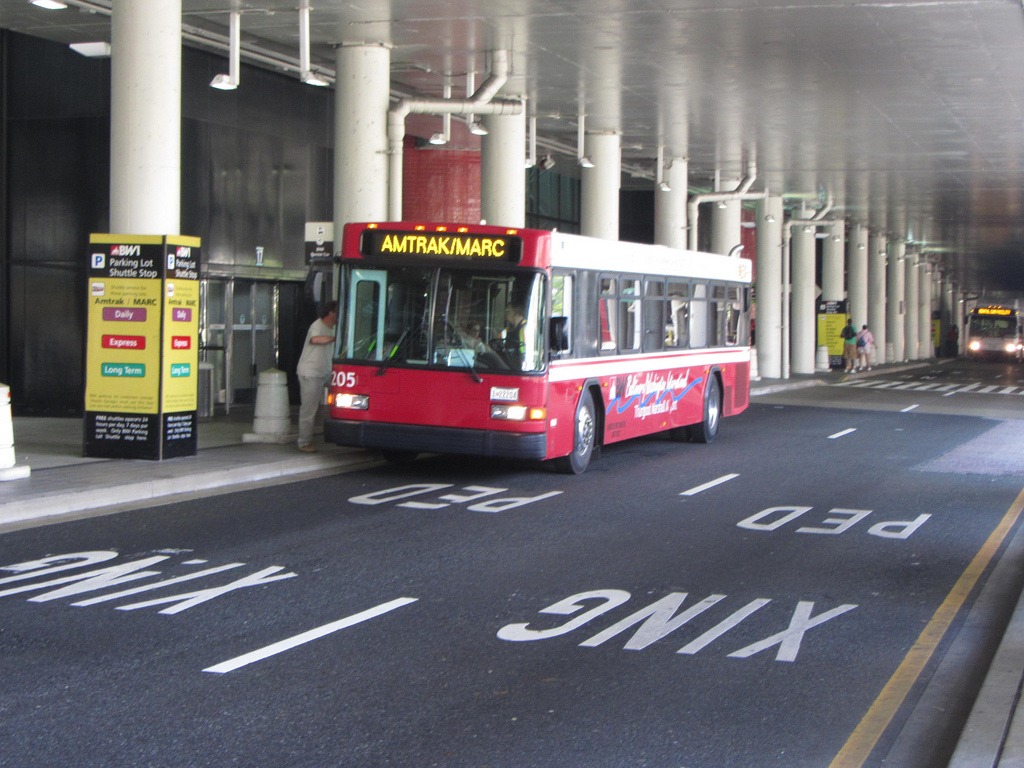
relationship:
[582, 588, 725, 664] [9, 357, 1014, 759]
letter on road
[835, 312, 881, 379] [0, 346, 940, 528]
people on sidewalk